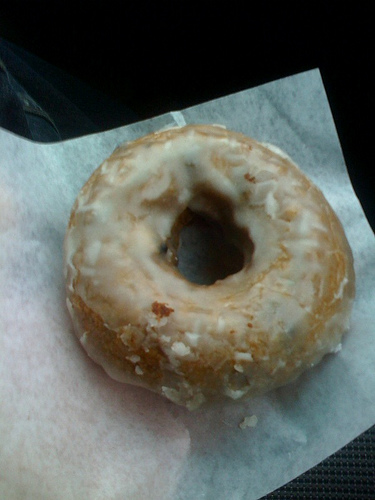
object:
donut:
[53, 132, 366, 407]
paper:
[0, 106, 370, 491]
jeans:
[2, 23, 153, 122]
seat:
[234, 423, 374, 500]